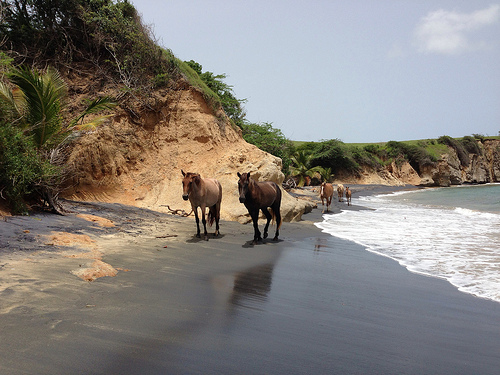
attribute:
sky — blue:
[132, 1, 500, 141]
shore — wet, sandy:
[312, 186, 425, 375]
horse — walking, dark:
[233, 173, 282, 246]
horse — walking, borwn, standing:
[319, 183, 334, 215]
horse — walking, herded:
[337, 184, 345, 202]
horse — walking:
[345, 187, 353, 206]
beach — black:
[1, 184, 500, 375]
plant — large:
[8, 64, 64, 150]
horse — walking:
[179, 170, 222, 242]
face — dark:
[235, 172, 251, 205]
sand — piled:
[53, 231, 118, 280]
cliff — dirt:
[6, 29, 305, 225]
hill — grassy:
[287, 139, 498, 161]